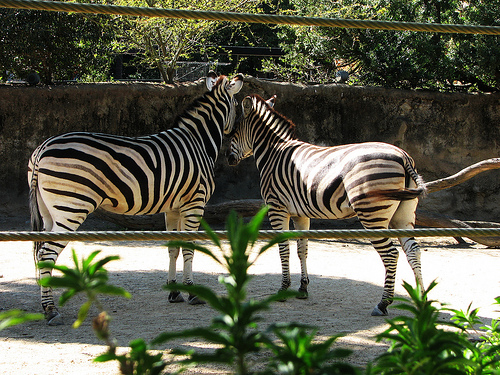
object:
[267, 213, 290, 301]
legs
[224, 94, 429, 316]
zebra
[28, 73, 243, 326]
zebra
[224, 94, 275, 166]
heads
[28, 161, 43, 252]
tail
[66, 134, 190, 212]
stripe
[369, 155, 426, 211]
tail